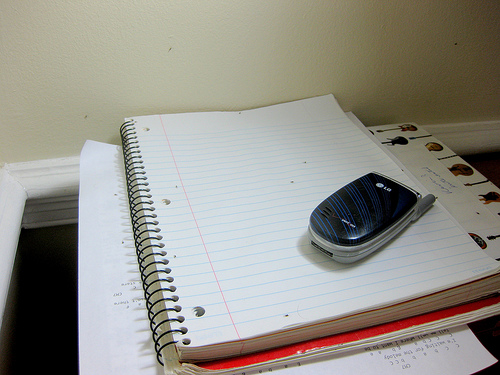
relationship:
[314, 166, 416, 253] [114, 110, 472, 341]
cellphone on notebook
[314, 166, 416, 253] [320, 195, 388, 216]
cellphone has cover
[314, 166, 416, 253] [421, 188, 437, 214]
cellphone has antenna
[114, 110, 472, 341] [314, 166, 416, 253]
notebook under cellphone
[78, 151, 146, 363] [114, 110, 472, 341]
sheet under notebook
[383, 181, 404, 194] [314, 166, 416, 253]
lg on cellphone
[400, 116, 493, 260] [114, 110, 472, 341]
sticker under notebook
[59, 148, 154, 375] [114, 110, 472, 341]
paper under note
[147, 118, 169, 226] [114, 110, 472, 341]
holes in notebook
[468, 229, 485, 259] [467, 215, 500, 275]
man on stamp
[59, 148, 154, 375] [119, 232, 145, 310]
paper has words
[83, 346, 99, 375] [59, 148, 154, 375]
spot on paper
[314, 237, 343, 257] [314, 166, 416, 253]
edge of cellphone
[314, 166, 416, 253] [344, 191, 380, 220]
cellphone has lines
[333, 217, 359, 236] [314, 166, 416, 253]
words on cellphone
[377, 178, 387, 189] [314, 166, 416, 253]
circle on cellphone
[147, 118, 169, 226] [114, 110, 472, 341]
holes on notebook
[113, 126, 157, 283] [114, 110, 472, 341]
spiral on notebook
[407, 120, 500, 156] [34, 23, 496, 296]
edge of room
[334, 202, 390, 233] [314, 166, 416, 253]
stripes on cellphone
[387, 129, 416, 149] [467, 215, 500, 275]
person on stamp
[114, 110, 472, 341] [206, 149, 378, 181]
notebook has lines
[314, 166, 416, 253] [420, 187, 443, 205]
cellphone has tip